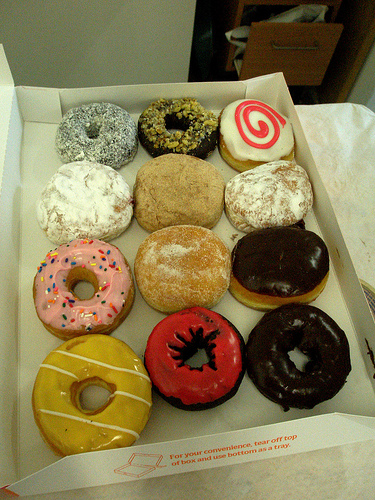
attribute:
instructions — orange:
[147, 425, 328, 476]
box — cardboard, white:
[3, 69, 374, 490]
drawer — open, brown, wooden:
[241, 2, 335, 86]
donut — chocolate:
[236, 298, 362, 413]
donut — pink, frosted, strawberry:
[27, 238, 137, 335]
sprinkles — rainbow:
[36, 239, 125, 326]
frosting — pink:
[31, 240, 137, 332]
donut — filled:
[35, 159, 137, 241]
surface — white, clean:
[5, 0, 192, 83]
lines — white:
[25, 347, 153, 443]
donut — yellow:
[24, 338, 150, 455]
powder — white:
[230, 164, 317, 229]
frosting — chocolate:
[243, 303, 354, 408]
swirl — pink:
[228, 98, 290, 150]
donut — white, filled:
[219, 96, 299, 165]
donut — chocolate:
[144, 308, 251, 414]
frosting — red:
[146, 305, 249, 410]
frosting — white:
[219, 98, 298, 164]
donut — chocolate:
[141, 95, 218, 158]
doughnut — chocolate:
[53, 102, 139, 165]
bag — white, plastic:
[230, 6, 334, 68]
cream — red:
[144, 305, 243, 405]